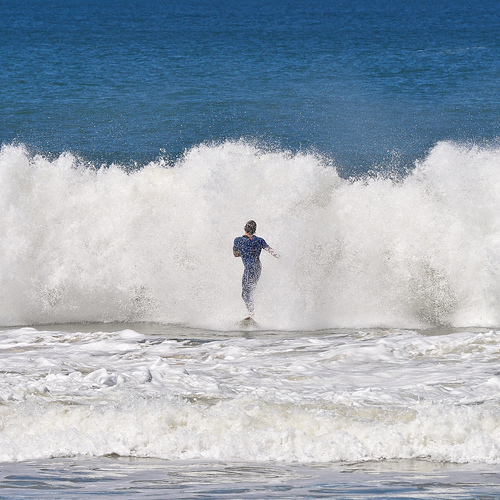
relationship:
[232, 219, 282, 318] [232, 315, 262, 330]
man on surfboard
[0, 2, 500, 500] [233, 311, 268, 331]
water on board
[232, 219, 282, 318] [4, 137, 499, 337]
man on wave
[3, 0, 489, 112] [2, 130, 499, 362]
calm/blue water on wave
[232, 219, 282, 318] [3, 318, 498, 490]
man on ocean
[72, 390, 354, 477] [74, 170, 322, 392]
foam on waves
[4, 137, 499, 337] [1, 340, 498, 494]
wave on shore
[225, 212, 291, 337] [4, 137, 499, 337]
man on wave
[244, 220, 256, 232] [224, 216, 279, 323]
hair on man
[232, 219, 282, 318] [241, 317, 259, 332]
man on surfboard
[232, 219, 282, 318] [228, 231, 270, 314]
man wears wet suit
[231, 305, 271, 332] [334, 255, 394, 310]
board has portion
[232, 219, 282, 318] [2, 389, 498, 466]
man next wave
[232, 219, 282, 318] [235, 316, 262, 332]
man on board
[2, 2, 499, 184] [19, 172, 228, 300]
water behind wave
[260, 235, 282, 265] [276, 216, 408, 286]
arm in water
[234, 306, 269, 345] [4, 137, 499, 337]
surfing into wave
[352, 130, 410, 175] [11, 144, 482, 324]
spray above wave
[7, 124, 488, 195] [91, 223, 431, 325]
spray coming up from wave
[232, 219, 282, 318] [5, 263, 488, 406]
man riding waves